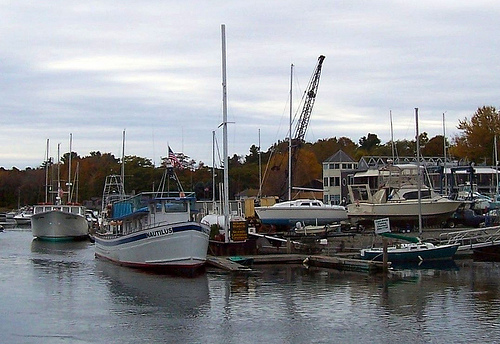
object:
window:
[334, 176, 341, 186]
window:
[330, 195, 337, 205]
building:
[321, 143, 358, 206]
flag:
[168, 144, 186, 170]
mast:
[219, 28, 229, 240]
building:
[243, 196, 256, 218]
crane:
[288, 54, 329, 139]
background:
[24, 27, 456, 223]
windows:
[35, 207, 43, 216]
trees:
[74, 154, 110, 202]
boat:
[32, 133, 86, 241]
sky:
[48, 41, 179, 127]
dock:
[209, 154, 494, 275]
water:
[49, 275, 234, 329]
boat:
[89, 221, 207, 268]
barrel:
[234, 220, 248, 241]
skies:
[222, 16, 451, 73]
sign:
[374, 218, 391, 235]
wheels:
[449, 221, 455, 228]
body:
[62, 264, 461, 344]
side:
[121, 232, 164, 259]